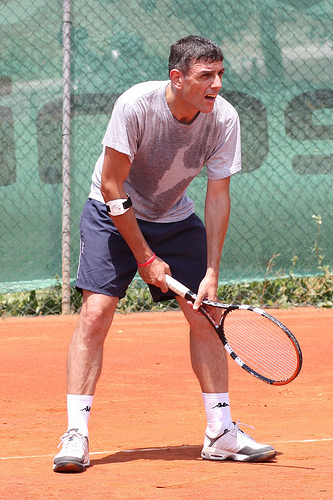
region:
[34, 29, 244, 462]
this is a tennis player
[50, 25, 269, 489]
the player is tired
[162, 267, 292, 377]
this is a racket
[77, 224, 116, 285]
this is a short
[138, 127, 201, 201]
this is the t shirt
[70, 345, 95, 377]
this is the leg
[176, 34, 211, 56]
this is the hair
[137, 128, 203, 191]
the t shirt is wet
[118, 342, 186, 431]
this is the pitch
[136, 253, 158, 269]
this is a wrist band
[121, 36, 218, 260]
the man is sweating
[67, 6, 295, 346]
dark hair is damp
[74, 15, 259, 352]
his mouth is open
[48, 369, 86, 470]
the shoes are white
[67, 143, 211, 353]
the shorts are blue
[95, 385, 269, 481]
the court is clay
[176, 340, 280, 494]
his socks are white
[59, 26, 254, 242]
the t shirt is grey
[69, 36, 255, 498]
he is playing tennis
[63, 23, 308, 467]
he holds a racket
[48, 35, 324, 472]
The man tennis player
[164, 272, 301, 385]
A racket black and white tennis racket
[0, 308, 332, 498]
A bare dirt tennis court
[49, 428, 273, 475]
The black and white snickers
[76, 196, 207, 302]
The dark blue pair of shorts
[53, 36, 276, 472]
The sweaty tennis player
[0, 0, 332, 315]
A meshed wire fenced court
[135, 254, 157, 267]
A red arm band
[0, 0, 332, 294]
The green tennis background court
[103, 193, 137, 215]
A black and white arm band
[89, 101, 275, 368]
a man playing tennis ball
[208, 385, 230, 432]
the socks are white in color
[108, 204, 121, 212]
the watch is white in color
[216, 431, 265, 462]
the shoes are white in color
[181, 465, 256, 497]
the floor is brown and sandy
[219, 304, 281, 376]
the teniss net is white in color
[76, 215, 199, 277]
the short is dark blue in color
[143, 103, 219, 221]
the shirt is full of sweat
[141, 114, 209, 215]
the shirt is grey in color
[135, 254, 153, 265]
the bracelate is red in color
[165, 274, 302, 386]
black and white tennis racquet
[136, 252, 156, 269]
red band on wrist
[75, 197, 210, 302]
navy blue cotton shorts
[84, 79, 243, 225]
grey cotton tee shirt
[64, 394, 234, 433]
white and black socks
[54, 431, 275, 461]
white and grey sneakers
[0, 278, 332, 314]
green plants by fence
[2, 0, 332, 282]
metal chain link fence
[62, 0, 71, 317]
grey metal fence post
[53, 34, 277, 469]
man playing on tennis court